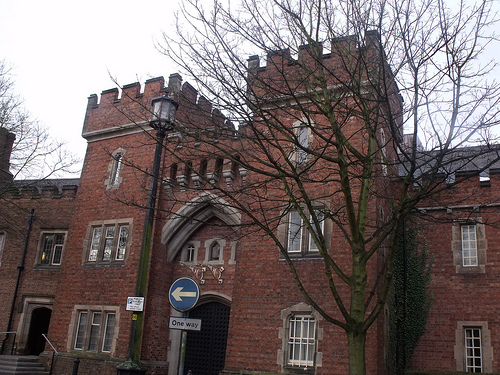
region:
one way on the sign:
[167, 315, 203, 334]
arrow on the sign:
[165, 271, 202, 313]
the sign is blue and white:
[170, 275, 202, 310]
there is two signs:
[165, 277, 206, 335]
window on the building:
[287, 306, 318, 365]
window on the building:
[105, 149, 127, 189]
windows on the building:
[73, 309, 119, 354]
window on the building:
[458, 327, 487, 374]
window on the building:
[452, 220, 482, 268]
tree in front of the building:
[162, 3, 497, 373]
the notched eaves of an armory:
[74, 23, 394, 147]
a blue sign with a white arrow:
[165, 278, 203, 313]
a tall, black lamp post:
[107, 88, 172, 372]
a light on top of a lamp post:
[138, 82, 196, 133]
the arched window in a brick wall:
[91, 139, 133, 199]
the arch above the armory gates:
[154, 188, 254, 258]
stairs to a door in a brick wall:
[5, 293, 69, 373]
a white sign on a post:
[118, 296, 148, 311]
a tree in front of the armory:
[131, 3, 498, 373]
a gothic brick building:
[0, 26, 497, 368]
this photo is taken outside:
[16, 51, 397, 366]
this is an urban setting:
[55, 59, 444, 362]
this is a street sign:
[154, 268, 213, 328]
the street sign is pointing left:
[166, 273, 208, 313]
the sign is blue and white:
[157, 255, 230, 315]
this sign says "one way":
[162, 300, 213, 336]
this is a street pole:
[120, 90, 218, 178]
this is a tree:
[213, 45, 428, 327]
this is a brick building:
[87, 124, 311, 319]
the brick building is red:
[62, 98, 299, 362]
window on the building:
[281, 210, 303, 255]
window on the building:
[310, 213, 320, 255]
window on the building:
[210, 242, 224, 259]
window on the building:
[180, 251, 194, 260]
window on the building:
[118, 231, 128, 258]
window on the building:
[105, 224, 112, 256]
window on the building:
[91, 233, 99, 259]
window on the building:
[104, 313, 117, 351]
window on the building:
[93, 315, 99, 348]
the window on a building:
[457, 320, 491, 372]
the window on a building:
[280, 305, 327, 367]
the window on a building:
[450, 220, 483, 272]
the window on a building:
[280, 200, 328, 260]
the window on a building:
[290, 112, 313, 162]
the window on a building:
[102, 142, 127, 198]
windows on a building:
[85, 215, 131, 272]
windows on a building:
[68, 300, 119, 352]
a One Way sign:
[160, 270, 210, 372]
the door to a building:
[19, 294, 54, 353]